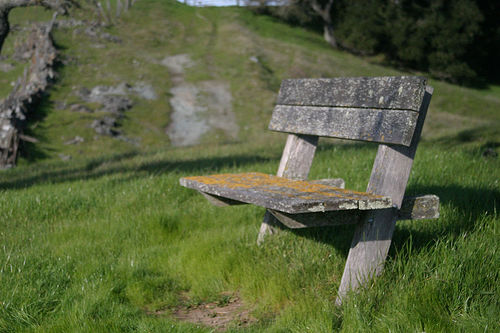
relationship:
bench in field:
[181, 71, 443, 309] [0, 1, 499, 329]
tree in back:
[305, 2, 341, 53] [7, 4, 500, 164]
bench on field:
[181, 71, 443, 309] [0, 1, 499, 329]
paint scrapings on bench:
[287, 194, 393, 218] [181, 71, 443, 309]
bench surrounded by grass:
[181, 71, 443, 309] [21, 136, 489, 313]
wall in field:
[11, 22, 80, 189] [0, 1, 499, 329]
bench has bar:
[181, 71, 443, 309] [329, 141, 414, 309]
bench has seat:
[181, 71, 443, 309] [181, 166, 398, 224]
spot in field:
[163, 287, 261, 328] [0, 1, 499, 329]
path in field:
[151, 38, 246, 159] [0, 1, 499, 329]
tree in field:
[305, 2, 341, 53] [0, 1, 499, 329]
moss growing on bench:
[179, 173, 378, 198] [181, 71, 443, 309]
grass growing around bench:
[21, 136, 489, 313] [181, 71, 443, 309]